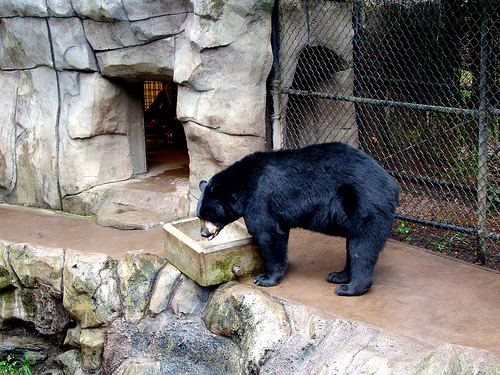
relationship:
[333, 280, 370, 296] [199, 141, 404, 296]
left paw on bear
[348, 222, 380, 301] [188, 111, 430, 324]
leg on bear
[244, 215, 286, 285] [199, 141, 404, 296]
leg on bear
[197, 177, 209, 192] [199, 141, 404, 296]
ear on bear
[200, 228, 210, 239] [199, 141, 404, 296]
nose on bear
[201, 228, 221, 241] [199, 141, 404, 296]
mouth on bear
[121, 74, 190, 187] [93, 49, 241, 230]
entrance to cave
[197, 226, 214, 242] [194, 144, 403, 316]
nose on bear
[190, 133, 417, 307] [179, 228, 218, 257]
bear drinking water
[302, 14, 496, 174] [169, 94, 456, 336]
fence behind bear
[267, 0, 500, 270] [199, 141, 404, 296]
fence behind bear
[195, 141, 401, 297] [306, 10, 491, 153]
bear behind fence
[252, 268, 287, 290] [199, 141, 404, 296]
paw on bear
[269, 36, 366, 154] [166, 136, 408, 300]
entrance for bear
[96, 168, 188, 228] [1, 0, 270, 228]
rock step into cave